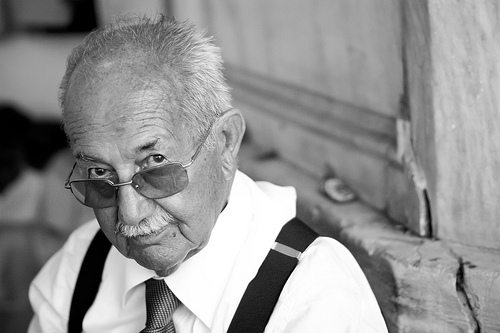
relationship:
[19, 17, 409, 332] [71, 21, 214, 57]
man has hair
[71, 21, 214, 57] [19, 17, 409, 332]
hair of man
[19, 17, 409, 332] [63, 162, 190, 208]
man wearing glasses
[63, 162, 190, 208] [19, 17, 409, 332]
glasses of man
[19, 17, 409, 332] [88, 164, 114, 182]
man has eye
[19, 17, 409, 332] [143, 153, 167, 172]
man has eye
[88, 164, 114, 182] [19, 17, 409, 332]
eye of man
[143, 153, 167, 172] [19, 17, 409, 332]
eye of man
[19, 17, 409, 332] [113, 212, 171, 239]
man has moustache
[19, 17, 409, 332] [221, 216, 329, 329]
man wearing suspender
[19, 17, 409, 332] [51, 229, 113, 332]
man wearing suspender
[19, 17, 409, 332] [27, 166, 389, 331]
man wearing shirt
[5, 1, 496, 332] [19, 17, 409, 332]
photo of man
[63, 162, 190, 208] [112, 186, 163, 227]
glasses on nose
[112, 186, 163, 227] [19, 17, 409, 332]
nose of man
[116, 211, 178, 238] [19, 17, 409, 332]
mustache of man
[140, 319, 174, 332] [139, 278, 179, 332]
knot of necktie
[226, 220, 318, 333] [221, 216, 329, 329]
strap of suspender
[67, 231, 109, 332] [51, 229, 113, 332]
strap of suspender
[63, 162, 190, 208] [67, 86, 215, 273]
glasses on face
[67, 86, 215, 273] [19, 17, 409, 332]
face of man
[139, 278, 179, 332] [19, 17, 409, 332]
tie on man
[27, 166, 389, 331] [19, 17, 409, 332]
shirt on man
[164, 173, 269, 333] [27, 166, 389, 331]
collar of shirt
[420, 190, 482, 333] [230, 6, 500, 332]
crack in wall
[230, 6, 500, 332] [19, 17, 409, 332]
wall behind man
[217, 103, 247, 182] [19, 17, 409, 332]
ear of man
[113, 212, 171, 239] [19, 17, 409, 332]
moustache on man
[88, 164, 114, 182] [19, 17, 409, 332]
eye on man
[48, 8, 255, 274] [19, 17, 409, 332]
head of man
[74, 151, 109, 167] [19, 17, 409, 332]
eyebrow of man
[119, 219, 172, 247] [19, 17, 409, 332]
mouth of man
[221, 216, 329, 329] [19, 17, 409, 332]
suspender on man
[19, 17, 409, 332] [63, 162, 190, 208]
man peering over glasses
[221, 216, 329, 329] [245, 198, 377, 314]
suspender on shoulder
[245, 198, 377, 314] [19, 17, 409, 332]
shoulder of man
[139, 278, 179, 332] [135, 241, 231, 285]
tie on neck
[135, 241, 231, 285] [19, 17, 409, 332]
neck of man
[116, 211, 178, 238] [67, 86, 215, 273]
mustache on face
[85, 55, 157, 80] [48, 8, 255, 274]
top of head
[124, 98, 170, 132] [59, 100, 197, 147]
creases on forhead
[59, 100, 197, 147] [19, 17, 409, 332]
forhead of man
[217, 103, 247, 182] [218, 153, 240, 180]
ear with lobe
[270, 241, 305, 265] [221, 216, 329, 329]
metal on suspender